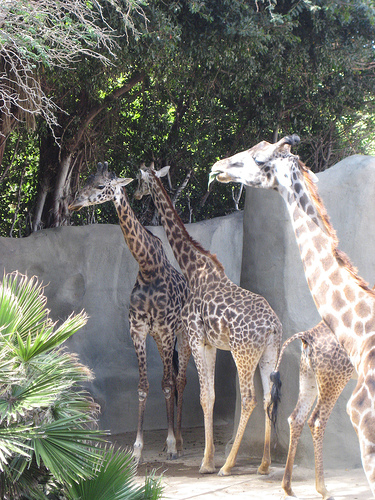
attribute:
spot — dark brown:
[205, 308, 222, 329]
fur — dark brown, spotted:
[115, 197, 125, 213]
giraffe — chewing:
[207, 133, 373, 427]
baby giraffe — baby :
[266, 320, 357, 499]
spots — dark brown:
[132, 227, 171, 273]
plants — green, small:
[1, 266, 167, 498]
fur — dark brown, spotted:
[163, 189, 191, 220]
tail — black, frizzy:
[265, 366, 282, 430]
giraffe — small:
[202, 124, 371, 498]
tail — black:
[264, 330, 308, 437]